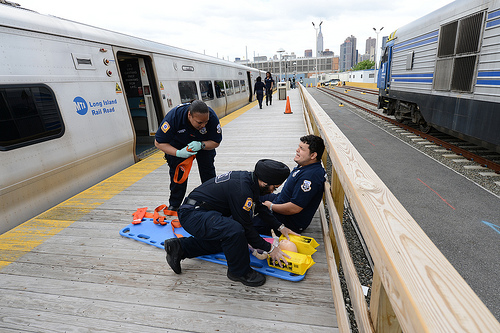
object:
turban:
[254, 158, 290, 184]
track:
[314, 83, 500, 187]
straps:
[132, 204, 185, 238]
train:
[0, 0, 279, 232]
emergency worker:
[164, 159, 301, 287]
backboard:
[119, 218, 306, 282]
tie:
[442, 154, 465, 159]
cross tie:
[425, 145, 453, 152]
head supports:
[267, 233, 319, 275]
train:
[377, 0, 500, 152]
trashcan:
[277, 82, 286, 100]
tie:
[259, 175, 299, 216]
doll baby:
[252, 229, 298, 260]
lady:
[254, 76, 268, 110]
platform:
[223, 107, 287, 161]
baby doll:
[266, 234, 319, 275]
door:
[116, 50, 164, 163]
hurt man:
[230, 134, 327, 236]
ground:
[0, 82, 500, 333]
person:
[154, 99, 222, 216]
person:
[254, 72, 274, 110]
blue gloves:
[176, 141, 201, 158]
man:
[164, 134, 325, 287]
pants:
[177, 204, 251, 277]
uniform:
[155, 103, 223, 146]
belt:
[186, 199, 209, 210]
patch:
[301, 180, 312, 193]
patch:
[243, 197, 254, 211]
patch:
[161, 122, 171, 134]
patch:
[217, 124, 222, 133]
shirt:
[273, 161, 326, 232]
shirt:
[188, 170, 282, 252]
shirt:
[155, 103, 223, 150]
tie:
[317, 88, 500, 187]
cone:
[284, 96, 293, 114]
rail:
[316, 85, 500, 173]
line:
[1, 92, 277, 269]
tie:
[417, 141, 435, 144]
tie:
[462, 165, 484, 169]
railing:
[298, 83, 500, 333]